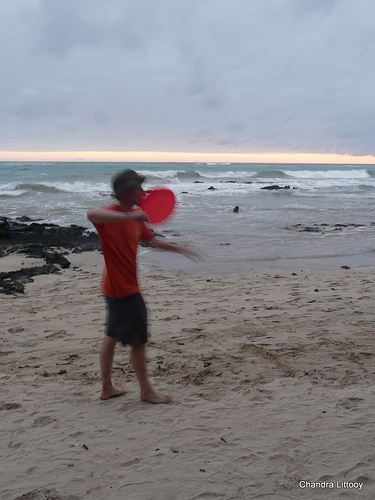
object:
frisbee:
[140, 185, 175, 223]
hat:
[110, 168, 146, 194]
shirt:
[92, 204, 154, 299]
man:
[85, 169, 205, 403]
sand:
[160, 277, 359, 391]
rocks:
[0, 215, 164, 255]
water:
[0, 162, 375, 232]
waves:
[249, 201, 365, 213]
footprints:
[38, 366, 68, 379]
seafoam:
[68, 182, 104, 192]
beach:
[0, 262, 375, 499]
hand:
[131, 207, 151, 224]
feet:
[100, 385, 130, 401]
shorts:
[104, 292, 148, 345]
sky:
[0, 0, 375, 152]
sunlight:
[0, 150, 375, 164]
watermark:
[298, 481, 364, 490]